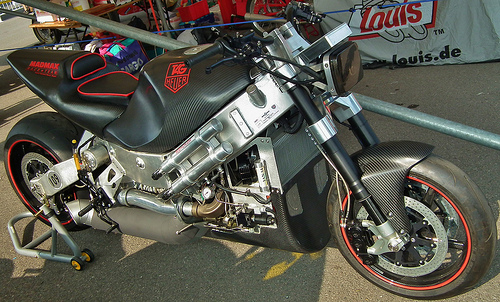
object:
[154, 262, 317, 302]
floor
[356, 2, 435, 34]
sign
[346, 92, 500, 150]
pipe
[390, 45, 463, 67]
object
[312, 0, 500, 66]
banner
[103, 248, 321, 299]
shadows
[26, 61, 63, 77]
red lettering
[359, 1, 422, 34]
red lettering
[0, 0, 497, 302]
black motorcycle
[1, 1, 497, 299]
bike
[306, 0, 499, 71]
cloth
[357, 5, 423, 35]
words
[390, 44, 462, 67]
words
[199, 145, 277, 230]
engine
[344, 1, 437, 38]
logo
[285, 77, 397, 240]
spoke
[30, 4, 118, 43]
table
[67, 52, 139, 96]
seat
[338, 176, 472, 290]
stripe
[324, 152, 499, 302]
tire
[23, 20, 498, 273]
bike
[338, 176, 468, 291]
rim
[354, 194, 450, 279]
disc brake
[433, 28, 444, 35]
symbol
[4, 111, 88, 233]
tire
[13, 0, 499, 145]
pole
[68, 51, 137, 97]
trim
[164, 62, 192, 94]
design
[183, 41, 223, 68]
handles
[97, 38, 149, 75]
bags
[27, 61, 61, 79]
words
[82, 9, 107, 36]
part